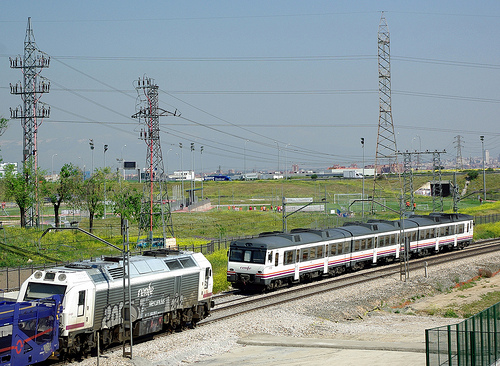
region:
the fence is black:
[435, 332, 454, 358]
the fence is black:
[427, 335, 444, 365]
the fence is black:
[432, 328, 447, 363]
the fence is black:
[429, 334, 441, 351]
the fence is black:
[436, 341, 448, 363]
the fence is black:
[439, 348, 447, 360]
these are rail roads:
[11, 226, 498, 364]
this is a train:
[221, 198, 479, 290]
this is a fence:
[423, 295, 498, 365]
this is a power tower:
[127, 70, 184, 200]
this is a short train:
[11, 242, 226, 359]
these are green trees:
[4, 162, 180, 249]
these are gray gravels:
[240, 308, 260, 324]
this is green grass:
[220, 215, 235, 230]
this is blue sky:
[306, 85, 330, 130]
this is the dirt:
[438, 292, 440, 301]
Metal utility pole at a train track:
[137, 71, 184, 248]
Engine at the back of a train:
[33, 242, 217, 332]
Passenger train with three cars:
[226, 205, 484, 267]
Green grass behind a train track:
[186, 210, 279, 235]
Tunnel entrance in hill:
[427, 182, 456, 198]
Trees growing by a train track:
[13, 168, 175, 236]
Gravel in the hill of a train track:
[385, 280, 424, 298]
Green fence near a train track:
[418, 310, 495, 365]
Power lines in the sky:
[182, 44, 374, 130]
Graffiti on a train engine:
[103, 300, 147, 329]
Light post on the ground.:
[122, 70, 274, 272]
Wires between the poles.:
[67, 38, 289, 178]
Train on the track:
[215, 155, 424, 336]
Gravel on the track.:
[267, 283, 412, 358]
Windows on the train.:
[213, 215, 284, 272]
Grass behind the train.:
[221, 162, 492, 314]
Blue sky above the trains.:
[177, 23, 334, 131]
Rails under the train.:
[192, 230, 272, 337]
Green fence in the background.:
[405, 320, 477, 354]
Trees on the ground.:
[33, 162, 125, 221]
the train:
[208, 182, 276, 264]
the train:
[219, 217, 321, 360]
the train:
[198, 152, 287, 308]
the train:
[237, 259, 313, 292]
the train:
[181, 146, 351, 343]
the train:
[285, 128, 398, 363]